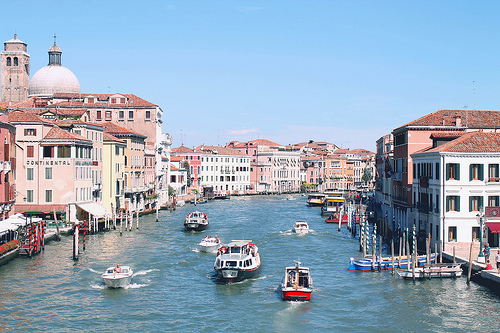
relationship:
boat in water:
[283, 214, 308, 237] [223, 205, 289, 242]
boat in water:
[284, 266, 308, 301] [225, 202, 275, 246]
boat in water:
[213, 240, 261, 285] [165, 283, 258, 313]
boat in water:
[184, 210, 209, 231] [143, 234, 195, 294]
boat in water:
[197, 235, 224, 253] [0, 191, 498, 332]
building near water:
[14, 122, 97, 218] [0, 191, 498, 332]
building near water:
[99, 133, 124, 216] [0, 191, 498, 332]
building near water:
[98, 121, 153, 213] [0, 191, 498, 332]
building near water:
[9, 92, 163, 209] [0, 191, 498, 332]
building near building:
[161, 131, 167, 206] [14, 122, 97, 218]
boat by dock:
[348, 252, 439, 271] [437, 245, 474, 262]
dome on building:
[27, 33, 80, 94] [19, 93, 163, 144]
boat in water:
[215, 237, 260, 282] [0, 191, 498, 332]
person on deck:
[464, 200, 490, 231] [427, 220, 480, 280]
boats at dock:
[346, 227, 466, 289] [440, 244, 497, 283]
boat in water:
[188, 208, 215, 238] [9, 196, 465, 326]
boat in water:
[86, 247, 137, 294] [9, 196, 465, 326]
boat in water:
[351, 223, 456, 277] [9, 196, 465, 326]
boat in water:
[213, 240, 261, 285] [5, 185, 454, 325]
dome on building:
[29, 36, 84, 98] [8, 40, 158, 230]